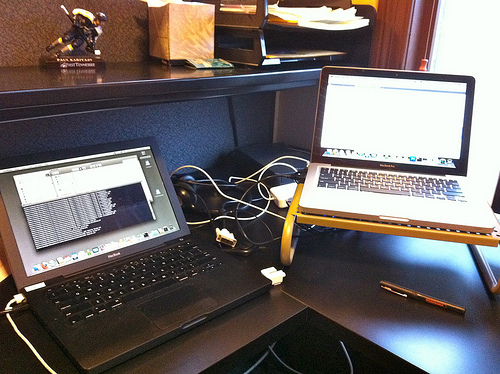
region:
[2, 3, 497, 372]
2 computer work station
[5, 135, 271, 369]
black lap top computer with screen on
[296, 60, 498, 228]
silver lap top computer with screen on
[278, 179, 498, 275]
yellow table to hold lap top higher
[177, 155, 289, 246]
disorganized mess of cords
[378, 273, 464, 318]
black pen with red writing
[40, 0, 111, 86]
small gold trophy for hockey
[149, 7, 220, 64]
box of opened tissues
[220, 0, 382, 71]
2 tiered basket for paperwork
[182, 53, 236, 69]
small booklet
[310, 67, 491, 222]
this is a laptop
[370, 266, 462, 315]
this is a pen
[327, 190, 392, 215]
the laptop is white in color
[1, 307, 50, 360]
this is a cable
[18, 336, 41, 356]
the cable is white in color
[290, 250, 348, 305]
this is the table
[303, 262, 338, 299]
the table is wooden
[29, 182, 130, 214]
this is the screen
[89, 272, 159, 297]
these are the buttons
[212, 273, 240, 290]
the laptop is black in color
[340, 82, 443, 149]
the laptop is on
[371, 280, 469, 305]
this is a pen on the table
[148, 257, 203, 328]
the laptop is black in color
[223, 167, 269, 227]
these are the wires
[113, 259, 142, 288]
the buttons are many in number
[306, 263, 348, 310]
this is the table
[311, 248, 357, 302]
the table is black in color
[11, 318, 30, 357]
the cable is long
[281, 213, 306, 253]
the stand is yellow in color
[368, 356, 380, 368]
edge of a table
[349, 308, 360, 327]
top of a table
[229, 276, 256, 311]
edge of a laptop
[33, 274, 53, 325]
part of a screen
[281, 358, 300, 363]
part of a cable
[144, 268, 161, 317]
part of a mouse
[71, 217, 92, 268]
edge of a screen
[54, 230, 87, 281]
part of a screen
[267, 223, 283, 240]
part of a board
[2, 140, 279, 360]
a black plastic open laptop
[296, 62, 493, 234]
a black and silver metal and plastic open laptop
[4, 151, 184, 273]
a laptop screen turned on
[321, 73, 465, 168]
a laptop screen turned on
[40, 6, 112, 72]
a hockey player statue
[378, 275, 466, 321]
a black and red pen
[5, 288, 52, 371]
a white computer cord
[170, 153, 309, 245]
a long white cord and charger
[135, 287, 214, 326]
the track pad of a laptop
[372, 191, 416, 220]
the track pad of a laptop